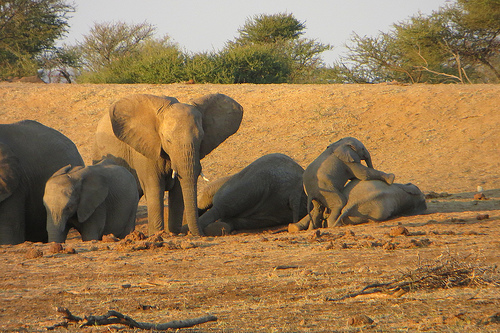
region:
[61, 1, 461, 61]
blue of daytime sky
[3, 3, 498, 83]
green leaves on trees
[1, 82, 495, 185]
dirt on side of hill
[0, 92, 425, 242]
herd of elephants outdoors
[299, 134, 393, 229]
baby elephant straddling another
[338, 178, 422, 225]
back of reclined elephant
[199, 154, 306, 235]
elephant laying in dirt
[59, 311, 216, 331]
broken branch on ground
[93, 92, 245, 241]
elephant standing on dirt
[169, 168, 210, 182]
two white ivory tusks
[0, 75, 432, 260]
A family of elephants that are relaxing on a sunny day.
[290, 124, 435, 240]
Baby elephants are playing and one is trying to nap.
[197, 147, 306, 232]
Napping elephant relaxing on the ground.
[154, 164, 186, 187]
Tusk of elephant all white iveroy.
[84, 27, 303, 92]
Savannah in background of trees from Africa.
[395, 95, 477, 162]
Dirt no plant life dusty brown ground.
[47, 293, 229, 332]
A broken stick on ground that is dryed up.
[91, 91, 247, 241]
Big elephant could be full grown male large ears.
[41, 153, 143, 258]
Baby elephant taking shade from larger elephant.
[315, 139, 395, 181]
Baby elephant moving on top of another elephant.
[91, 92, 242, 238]
An elephant standing in the savannah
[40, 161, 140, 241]
An small elephant standing in the savannah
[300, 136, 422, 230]
An elephant climbing atop another elephant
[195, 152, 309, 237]
An elephant laying down in the savannah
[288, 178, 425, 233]
An elephant laying down in the savannah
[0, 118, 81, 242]
An elephant standing in the savannah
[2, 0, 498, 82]
trees on a ridge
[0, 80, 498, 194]
A slope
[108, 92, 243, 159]
ears of an elephant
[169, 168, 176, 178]
an elephant tusk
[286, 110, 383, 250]
the elephant is playing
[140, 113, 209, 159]
elephant's eyes are closed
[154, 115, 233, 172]
elephant's eyes are closed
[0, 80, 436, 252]
Elephants are in the shot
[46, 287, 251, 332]
Wood on the ground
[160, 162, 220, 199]
These are white trunks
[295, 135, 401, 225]
A baby elephant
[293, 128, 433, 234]
Elephant on top of each other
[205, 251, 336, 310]
This is the ground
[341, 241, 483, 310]
More branches in the shot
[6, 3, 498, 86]
In the background, there are trees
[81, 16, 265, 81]
The leaves are green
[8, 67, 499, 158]
This is a hill